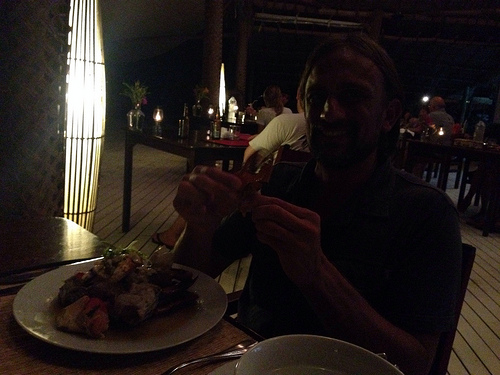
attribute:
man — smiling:
[266, 42, 419, 302]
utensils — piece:
[168, 344, 256, 370]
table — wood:
[40, 208, 98, 267]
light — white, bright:
[71, 11, 105, 226]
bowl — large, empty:
[234, 336, 397, 370]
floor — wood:
[91, 140, 178, 227]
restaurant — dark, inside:
[6, 0, 493, 329]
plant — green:
[122, 74, 143, 116]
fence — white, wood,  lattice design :
[8, 14, 67, 187]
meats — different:
[43, 259, 175, 339]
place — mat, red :
[209, 135, 253, 148]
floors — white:
[467, 229, 499, 370]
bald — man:
[421, 98, 452, 110]